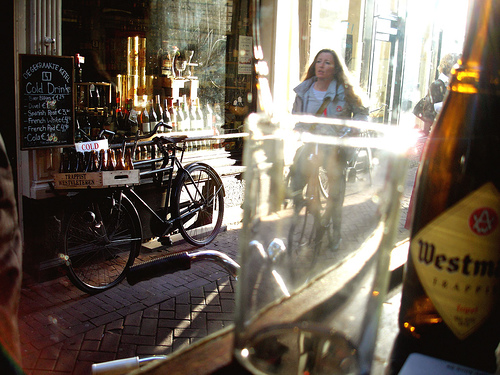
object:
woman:
[290, 49, 355, 245]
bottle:
[398, 1, 498, 361]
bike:
[55, 122, 227, 293]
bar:
[0, 1, 499, 373]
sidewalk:
[20, 167, 416, 374]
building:
[1, 0, 496, 272]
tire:
[57, 190, 147, 294]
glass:
[232, 119, 410, 372]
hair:
[308, 48, 348, 96]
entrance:
[361, 1, 402, 124]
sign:
[20, 51, 77, 153]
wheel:
[178, 167, 227, 246]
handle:
[97, 127, 120, 138]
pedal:
[158, 235, 171, 247]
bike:
[287, 150, 344, 279]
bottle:
[58, 151, 68, 175]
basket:
[54, 170, 140, 190]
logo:
[53, 172, 100, 186]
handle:
[161, 121, 173, 130]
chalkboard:
[17, 50, 81, 149]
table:
[131, 238, 497, 371]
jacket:
[291, 76, 358, 139]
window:
[62, 0, 259, 135]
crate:
[54, 165, 141, 191]